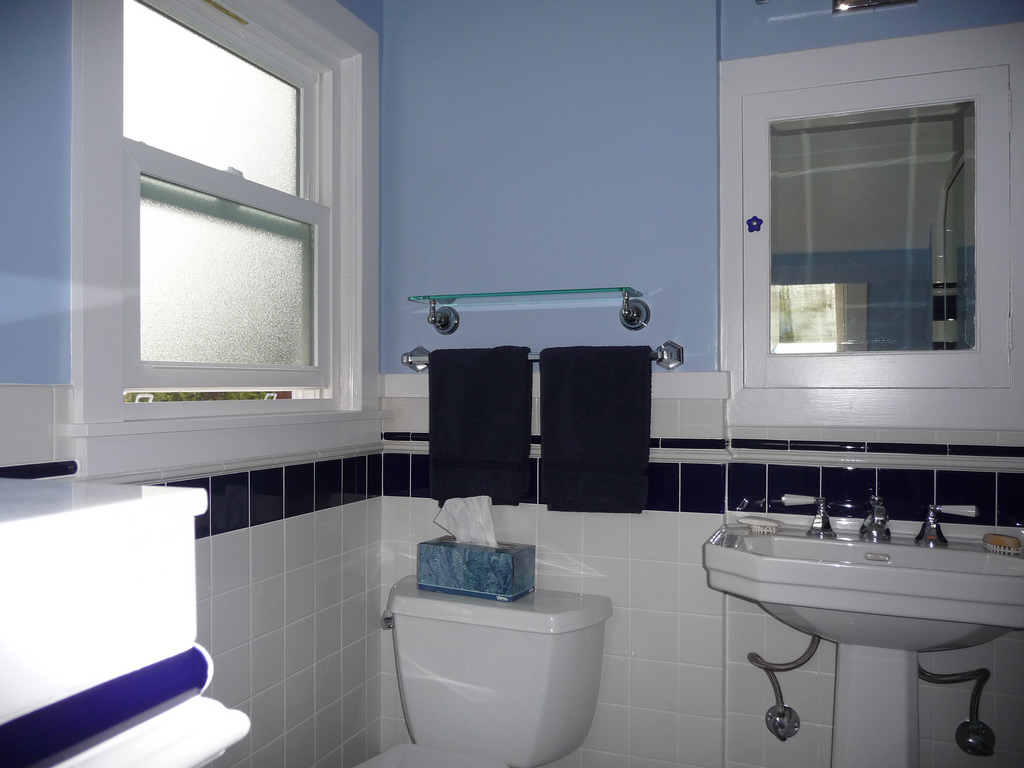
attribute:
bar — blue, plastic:
[0, 635, 217, 766]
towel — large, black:
[422, 342, 531, 508]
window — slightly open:
[117, 0, 375, 406]